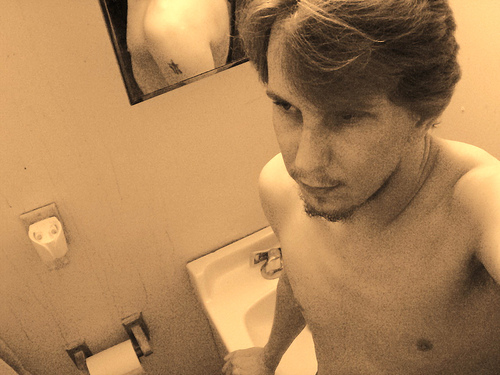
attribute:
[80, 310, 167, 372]
holder — toilet paper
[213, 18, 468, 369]
man — bare chested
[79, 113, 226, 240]
wall — part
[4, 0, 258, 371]
wall — part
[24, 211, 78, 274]
tissue paper — white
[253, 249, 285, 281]
handle — water , tap, silver , colored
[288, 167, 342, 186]
mustache — dark, hair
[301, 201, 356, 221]
goatee — dark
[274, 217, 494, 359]
chest — part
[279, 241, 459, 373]
chest — part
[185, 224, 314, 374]
sink — white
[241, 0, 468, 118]
hair — male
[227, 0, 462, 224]
head — man's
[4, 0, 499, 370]
wall — soap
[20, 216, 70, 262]
dispenser — hand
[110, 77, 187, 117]
corner — mirror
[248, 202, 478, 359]
chested — bare 